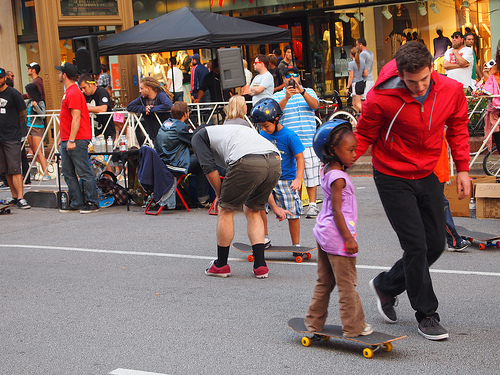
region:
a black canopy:
[82, 15, 312, 61]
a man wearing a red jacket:
[353, 68, 461, 196]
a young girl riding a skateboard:
[296, 119, 358, 347]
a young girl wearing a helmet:
[307, 118, 364, 168]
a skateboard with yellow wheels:
[276, 324, 406, 358]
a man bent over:
[172, 118, 272, 283]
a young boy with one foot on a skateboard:
[252, 96, 289, 270]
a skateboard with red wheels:
[218, 237, 319, 279]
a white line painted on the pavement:
[0, 241, 198, 263]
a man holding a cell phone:
[271, 68, 306, 105]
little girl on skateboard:
[270, 110, 430, 370]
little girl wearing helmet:
[314, 105, 355, 169]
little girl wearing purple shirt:
[308, 165, 366, 257]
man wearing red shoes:
[211, 242, 285, 286]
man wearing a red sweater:
[365, 55, 493, 203]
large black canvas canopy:
[90, 8, 304, 63]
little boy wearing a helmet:
[244, 92, 289, 130]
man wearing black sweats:
[370, 173, 471, 318]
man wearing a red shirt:
[51, 79, 102, 146]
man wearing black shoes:
[360, 262, 460, 349]